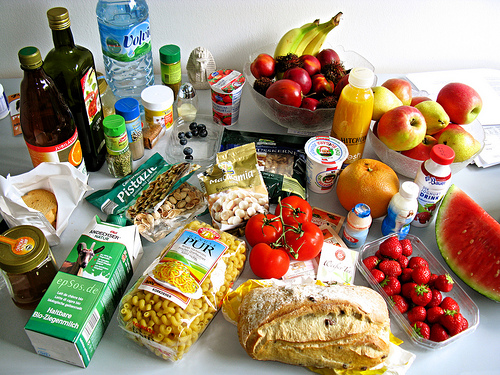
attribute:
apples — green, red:
[369, 80, 476, 177]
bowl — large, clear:
[240, 69, 345, 139]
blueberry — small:
[182, 147, 192, 157]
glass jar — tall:
[44, 16, 106, 166]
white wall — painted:
[30, 0, 370, 85]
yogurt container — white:
[300, 131, 337, 192]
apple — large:
[441, 81, 479, 125]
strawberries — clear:
[382, 242, 435, 304]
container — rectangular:
[370, 231, 473, 343]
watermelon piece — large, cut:
[430, 177, 498, 297]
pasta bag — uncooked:
[127, 216, 245, 352]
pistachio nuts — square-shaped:
[161, 174, 185, 196]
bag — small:
[94, 152, 204, 229]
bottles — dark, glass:
[7, 5, 112, 163]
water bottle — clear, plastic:
[82, 0, 166, 108]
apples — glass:
[390, 103, 460, 133]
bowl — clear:
[368, 131, 461, 192]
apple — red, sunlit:
[439, 79, 485, 128]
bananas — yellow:
[278, 17, 327, 49]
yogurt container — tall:
[205, 68, 245, 127]